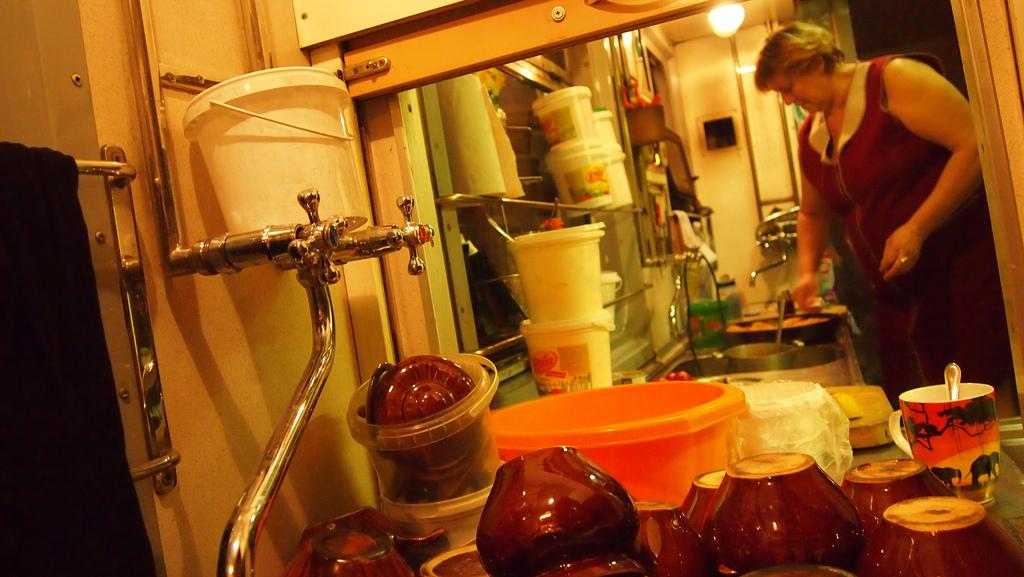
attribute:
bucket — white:
[176, 64, 377, 235]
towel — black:
[5, 132, 176, 569]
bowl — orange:
[482, 377, 748, 512]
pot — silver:
[723, 332, 843, 376]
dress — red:
[791, 63, 1018, 387]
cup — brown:
[471, 438, 645, 573]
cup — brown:
[698, 448, 846, 571]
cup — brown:
[857, 492, 1016, 563]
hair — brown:
[748, 19, 843, 80]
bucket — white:
[170, 52, 377, 244]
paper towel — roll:
[432, 63, 543, 245]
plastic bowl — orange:
[466, 318, 771, 547]